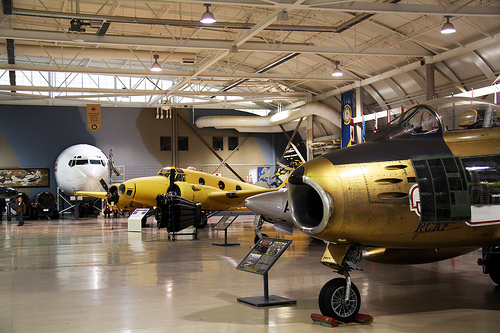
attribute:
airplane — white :
[48, 113, 157, 283]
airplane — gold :
[102, 103, 280, 288]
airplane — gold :
[132, 125, 240, 260]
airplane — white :
[32, 115, 122, 253]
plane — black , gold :
[76, 131, 296, 321]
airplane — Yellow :
[65, 117, 263, 299]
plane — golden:
[87, 120, 193, 270]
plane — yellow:
[68, 161, 283, 231]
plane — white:
[42, 140, 122, 202]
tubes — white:
[193, 101, 343, 133]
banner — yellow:
[84, 100, 102, 132]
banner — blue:
[336, 84, 362, 151]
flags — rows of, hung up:
[344, 106, 404, 131]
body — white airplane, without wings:
[53, 142, 111, 199]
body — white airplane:
[49, 144, 120, 195]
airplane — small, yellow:
[79, 169, 290, 233]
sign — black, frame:
[235, 234, 294, 273]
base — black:
[238, 273, 298, 306]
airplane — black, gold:
[246, 96, 484, 317]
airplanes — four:
[55, 98, 484, 318]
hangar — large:
[3, 4, 483, 328]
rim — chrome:
[331, 290, 358, 315]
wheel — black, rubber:
[315, 275, 363, 321]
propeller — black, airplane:
[99, 173, 120, 211]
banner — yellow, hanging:
[82, 100, 103, 131]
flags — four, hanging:
[349, 109, 392, 144]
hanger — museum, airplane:
[2, 3, 483, 328]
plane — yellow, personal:
[75, 170, 289, 230]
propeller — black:
[90, 173, 127, 213]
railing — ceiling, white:
[2, 3, 482, 98]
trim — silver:
[272, 173, 338, 221]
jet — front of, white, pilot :
[50, 140, 118, 192]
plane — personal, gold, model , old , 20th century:
[276, 88, 484, 315]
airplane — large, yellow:
[70, 159, 298, 244]